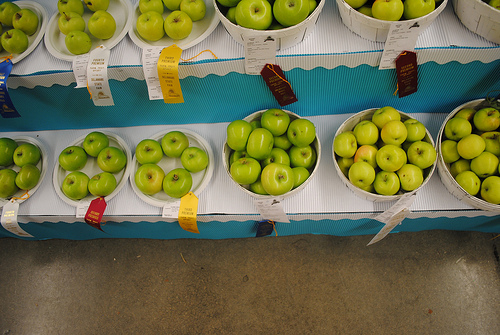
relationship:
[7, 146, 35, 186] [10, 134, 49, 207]
apples are on a plate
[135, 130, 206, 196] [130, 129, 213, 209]
apples are on a plate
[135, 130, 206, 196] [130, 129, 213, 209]
apples on a plate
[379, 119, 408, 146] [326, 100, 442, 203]
apple in bucket